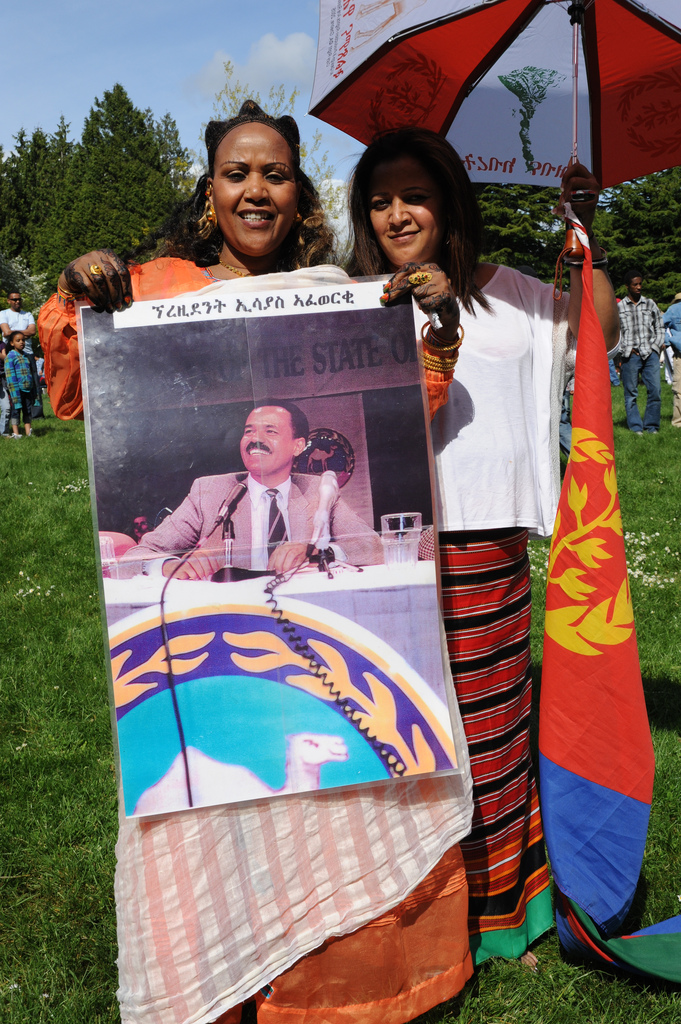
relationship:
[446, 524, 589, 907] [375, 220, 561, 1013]
stripes on dress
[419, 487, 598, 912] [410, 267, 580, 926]
stripe on dress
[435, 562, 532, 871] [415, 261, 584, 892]
stripe on dress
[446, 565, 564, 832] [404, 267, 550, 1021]
stripe on dress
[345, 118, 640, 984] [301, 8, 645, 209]
woman holding umbrella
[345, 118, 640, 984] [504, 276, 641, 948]
woman holding flag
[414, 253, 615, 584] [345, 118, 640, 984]
shirt on woman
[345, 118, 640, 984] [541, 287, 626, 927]
woman holding flag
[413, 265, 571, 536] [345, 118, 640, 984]
shirt on woman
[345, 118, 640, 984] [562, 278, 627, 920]
woman holding flag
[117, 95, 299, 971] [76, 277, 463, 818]
woman holding picture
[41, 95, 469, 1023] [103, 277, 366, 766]
woman holding poster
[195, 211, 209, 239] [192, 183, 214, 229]
earing in ear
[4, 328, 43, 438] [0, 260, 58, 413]
child with father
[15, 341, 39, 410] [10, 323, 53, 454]
sweater of child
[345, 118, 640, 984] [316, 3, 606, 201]
woman holding umbrella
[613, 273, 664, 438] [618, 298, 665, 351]
man wearing shirt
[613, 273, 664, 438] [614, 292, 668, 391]
man wearing shirt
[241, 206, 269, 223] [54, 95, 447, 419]
teeth of woman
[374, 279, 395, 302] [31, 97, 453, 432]
fingers of woman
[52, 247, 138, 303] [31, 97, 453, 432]
hand of woman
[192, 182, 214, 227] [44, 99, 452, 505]
ear of woman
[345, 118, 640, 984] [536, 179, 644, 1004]
woman holding umbrella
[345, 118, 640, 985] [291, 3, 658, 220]
woman holding umbrella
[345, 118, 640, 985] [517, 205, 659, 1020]
woman holding flag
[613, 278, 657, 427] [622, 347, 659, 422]
man in jeans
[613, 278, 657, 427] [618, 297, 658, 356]
man in shirt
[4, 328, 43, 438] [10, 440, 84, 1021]
child standing grass